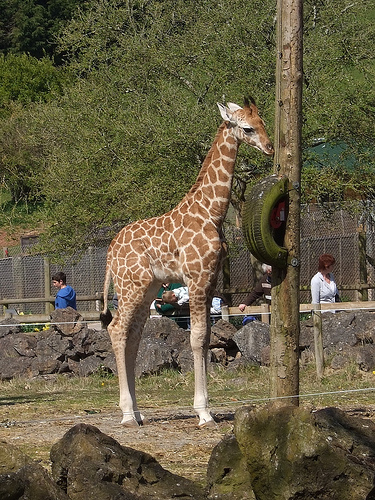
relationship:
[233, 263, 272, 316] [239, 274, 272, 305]
person wearing jacket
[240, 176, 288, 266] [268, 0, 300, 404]
tire on pole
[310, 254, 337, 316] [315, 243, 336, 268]
woman with hair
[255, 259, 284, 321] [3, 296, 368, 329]
man holding onto fence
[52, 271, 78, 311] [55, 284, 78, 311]
man in hoodie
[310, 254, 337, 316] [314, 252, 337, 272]
woman has red hair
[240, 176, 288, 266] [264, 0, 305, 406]
tire in post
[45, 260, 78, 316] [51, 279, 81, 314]
man in hoodie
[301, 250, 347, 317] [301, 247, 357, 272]
female with hair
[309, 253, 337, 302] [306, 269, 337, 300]
woman in shirt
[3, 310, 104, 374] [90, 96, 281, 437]
stone wall behind giraffe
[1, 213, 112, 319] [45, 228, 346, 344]
fence beyond people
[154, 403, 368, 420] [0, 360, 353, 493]
shadow cast onto ground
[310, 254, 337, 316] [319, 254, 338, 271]
woman with hair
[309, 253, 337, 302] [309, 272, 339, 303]
woman wearing shirt